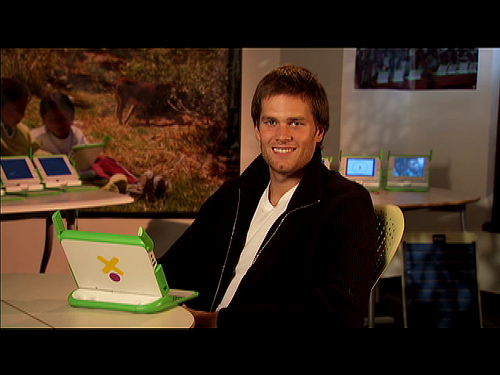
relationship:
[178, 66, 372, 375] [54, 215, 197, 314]
man using computer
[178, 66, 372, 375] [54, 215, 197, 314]
man has computer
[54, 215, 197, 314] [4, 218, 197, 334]
computer on table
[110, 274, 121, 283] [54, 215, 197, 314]
dot on computer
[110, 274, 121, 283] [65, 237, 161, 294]
dot on back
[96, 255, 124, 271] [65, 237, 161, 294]
cross on back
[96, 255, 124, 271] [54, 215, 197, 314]
cross on computer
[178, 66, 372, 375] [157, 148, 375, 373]
man has jacket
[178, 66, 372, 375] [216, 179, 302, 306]
man has shirt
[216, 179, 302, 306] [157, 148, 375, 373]
shirt under jacket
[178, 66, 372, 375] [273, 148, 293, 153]
man has teeth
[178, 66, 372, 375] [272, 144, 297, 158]
man has mouth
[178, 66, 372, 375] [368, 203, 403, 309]
man in chair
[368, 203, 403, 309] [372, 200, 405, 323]
chair has back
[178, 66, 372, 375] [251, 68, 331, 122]
man has hair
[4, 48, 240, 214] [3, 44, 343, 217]
photo on wall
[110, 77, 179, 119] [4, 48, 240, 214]
animal in photo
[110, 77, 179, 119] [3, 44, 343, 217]
animal on wall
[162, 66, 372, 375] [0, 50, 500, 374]
man in lab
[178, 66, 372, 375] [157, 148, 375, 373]
man wearing jacket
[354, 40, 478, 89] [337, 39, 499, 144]
photo on wall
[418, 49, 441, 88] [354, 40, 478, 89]
monkey in photo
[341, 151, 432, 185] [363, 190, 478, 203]
computers on table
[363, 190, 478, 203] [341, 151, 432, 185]
table has computers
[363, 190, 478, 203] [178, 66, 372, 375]
table behind man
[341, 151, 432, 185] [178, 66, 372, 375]
computers behind man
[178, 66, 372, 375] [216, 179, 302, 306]
man wearing shirt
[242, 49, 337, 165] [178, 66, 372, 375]
wall behind man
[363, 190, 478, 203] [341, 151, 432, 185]
table with computers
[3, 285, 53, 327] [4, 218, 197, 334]
line in table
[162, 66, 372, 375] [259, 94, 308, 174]
man has face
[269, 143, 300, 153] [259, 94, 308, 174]
smile on face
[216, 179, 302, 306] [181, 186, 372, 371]
shirt on body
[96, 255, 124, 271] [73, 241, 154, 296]
cross on cover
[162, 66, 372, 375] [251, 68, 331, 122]
man has hair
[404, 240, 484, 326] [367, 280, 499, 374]
bin on ground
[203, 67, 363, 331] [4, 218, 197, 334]
hunk at table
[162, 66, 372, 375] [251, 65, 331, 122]
man with hair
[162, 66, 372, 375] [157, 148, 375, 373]
man in jacket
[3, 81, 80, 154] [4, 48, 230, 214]
children in photo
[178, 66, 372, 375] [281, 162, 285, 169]
man with dimple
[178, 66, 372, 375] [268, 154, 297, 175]
man has chin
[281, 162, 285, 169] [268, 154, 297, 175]
dimple in chin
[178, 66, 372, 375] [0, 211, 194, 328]
man at desk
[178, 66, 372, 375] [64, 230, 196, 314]
man with computer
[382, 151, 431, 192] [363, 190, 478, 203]
computers on table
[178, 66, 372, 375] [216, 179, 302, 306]
man with shirt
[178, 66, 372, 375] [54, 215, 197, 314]
man with computer